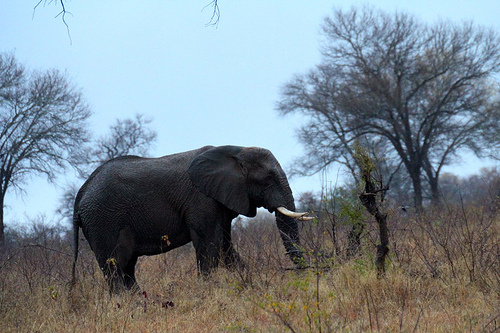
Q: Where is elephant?
A: In brush.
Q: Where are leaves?
A: No leaves.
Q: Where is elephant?
A: In wild.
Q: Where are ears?
A: On elephant.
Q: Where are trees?
A: Behind elephant.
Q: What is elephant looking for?
A: Food.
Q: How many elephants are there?
A: One.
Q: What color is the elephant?
A: Gray.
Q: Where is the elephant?
A: In the grass.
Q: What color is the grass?
A: Yellow and green.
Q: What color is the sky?
A: Blue.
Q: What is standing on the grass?
A: The elephant.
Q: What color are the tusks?
A: White.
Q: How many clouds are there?
A: None.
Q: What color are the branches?
A: Brown.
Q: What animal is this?
A: An elephant.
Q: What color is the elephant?
A: Gray.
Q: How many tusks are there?
A: Two.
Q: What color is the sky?
A: Blue.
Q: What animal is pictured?
A: An elephant.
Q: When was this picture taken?
A: Daytime.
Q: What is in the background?
A: Trees.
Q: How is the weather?
A: Clear.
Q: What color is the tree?
A: Green.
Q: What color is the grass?
A: Brown.